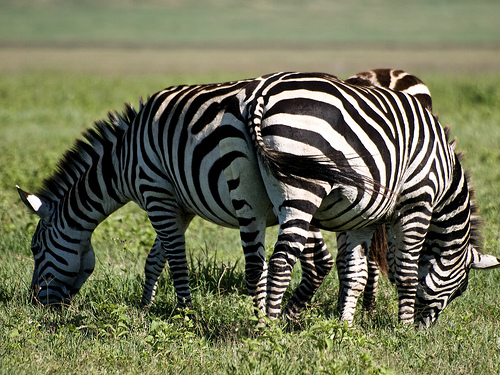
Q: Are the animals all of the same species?
A: Yes, all the animals are zebras.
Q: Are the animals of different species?
A: No, all the animals are zebras.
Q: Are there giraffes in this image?
A: No, there are no giraffes.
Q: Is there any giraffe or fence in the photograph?
A: No, there are no giraffes or fences.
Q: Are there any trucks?
A: No, there are no trucks.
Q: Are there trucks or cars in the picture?
A: No, there are no trucks or cars.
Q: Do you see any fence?
A: No, there are no fences.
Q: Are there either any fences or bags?
A: No, there are no fences or bags.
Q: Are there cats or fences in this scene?
A: No, there are no fences or cats.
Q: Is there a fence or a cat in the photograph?
A: No, there are no fences or cats.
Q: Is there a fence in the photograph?
A: No, there are no fences.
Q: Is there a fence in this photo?
A: No, there are no fences.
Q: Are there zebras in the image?
A: Yes, there is a zebra.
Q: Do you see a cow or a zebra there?
A: Yes, there is a zebra.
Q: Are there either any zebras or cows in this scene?
A: Yes, there is a zebra.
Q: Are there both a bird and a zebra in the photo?
A: No, there is a zebra but no birds.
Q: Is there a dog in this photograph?
A: No, there are no dogs.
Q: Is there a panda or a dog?
A: No, there are no dogs or pandas.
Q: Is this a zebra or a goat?
A: This is a zebra.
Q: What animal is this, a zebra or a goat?
A: This is a zebra.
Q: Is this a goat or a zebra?
A: This is a zebra.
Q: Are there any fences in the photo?
A: No, there are no fences.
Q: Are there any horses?
A: No, there are no horses.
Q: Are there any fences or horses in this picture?
A: No, there are no horses or fences.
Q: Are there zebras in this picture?
A: Yes, there is a zebra.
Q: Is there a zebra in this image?
A: Yes, there is a zebra.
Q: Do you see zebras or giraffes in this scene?
A: Yes, there is a zebra.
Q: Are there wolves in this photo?
A: No, there are no wolves.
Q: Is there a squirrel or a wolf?
A: No, there are no wolves or squirrels.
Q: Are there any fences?
A: No, there are no fences.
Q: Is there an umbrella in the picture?
A: No, there are no umbrellas.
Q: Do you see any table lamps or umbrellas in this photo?
A: No, there are no umbrellas or table lamps.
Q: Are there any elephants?
A: No, there are no elephants.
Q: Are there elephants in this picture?
A: No, there are no elephants.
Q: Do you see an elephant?
A: No, there are no elephants.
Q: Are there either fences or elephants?
A: No, there are no elephants or fences.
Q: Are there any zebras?
A: Yes, there is a zebra.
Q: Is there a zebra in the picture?
A: Yes, there is a zebra.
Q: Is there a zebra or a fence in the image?
A: Yes, there is a zebra.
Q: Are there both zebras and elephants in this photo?
A: No, there is a zebra but no elephants.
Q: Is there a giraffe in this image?
A: No, there are no giraffes.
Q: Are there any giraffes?
A: No, there are no giraffes.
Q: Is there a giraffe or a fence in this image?
A: No, there are no giraffes or fences.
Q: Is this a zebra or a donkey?
A: This is a zebra.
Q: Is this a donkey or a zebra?
A: This is a zebra.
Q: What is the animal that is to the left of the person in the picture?
A: The animal is a zebra.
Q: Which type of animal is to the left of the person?
A: The animal is a zebra.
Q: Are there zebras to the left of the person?
A: Yes, there is a zebra to the left of the person.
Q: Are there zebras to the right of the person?
A: No, the zebra is to the left of the person.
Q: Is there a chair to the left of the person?
A: No, there is a zebra to the left of the person.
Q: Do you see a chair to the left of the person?
A: No, there is a zebra to the left of the person.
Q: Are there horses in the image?
A: No, there are no horses.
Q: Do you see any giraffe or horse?
A: No, there are no horses or giraffes.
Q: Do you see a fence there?
A: No, there are no fences.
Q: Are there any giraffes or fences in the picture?
A: No, there are no fences or giraffes.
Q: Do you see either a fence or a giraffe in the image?
A: No, there are no fences or giraffes.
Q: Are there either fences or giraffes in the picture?
A: No, there are no fences or giraffes.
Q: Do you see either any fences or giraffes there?
A: No, there are no fences or giraffes.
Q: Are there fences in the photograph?
A: No, there are no fences.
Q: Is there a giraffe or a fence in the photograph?
A: No, there are no fences or giraffes.